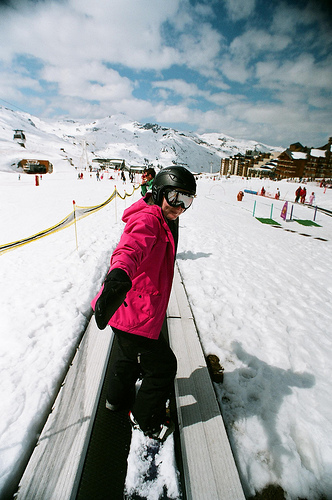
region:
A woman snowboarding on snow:
[96, 166, 197, 439]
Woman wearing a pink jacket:
[89, 167, 196, 340]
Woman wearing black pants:
[106, 328, 178, 443]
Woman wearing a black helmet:
[152, 164, 198, 207]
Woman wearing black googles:
[161, 187, 194, 210]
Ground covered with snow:
[0, 170, 331, 498]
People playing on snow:
[0, 168, 331, 210]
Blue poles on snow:
[251, 198, 275, 218]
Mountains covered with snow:
[0, 106, 275, 169]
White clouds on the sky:
[0, 0, 331, 133]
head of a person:
[141, 155, 212, 219]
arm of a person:
[107, 225, 146, 274]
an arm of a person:
[105, 227, 151, 281]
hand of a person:
[88, 270, 145, 320]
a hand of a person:
[80, 286, 134, 329]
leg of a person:
[114, 336, 192, 408]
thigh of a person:
[115, 325, 177, 369]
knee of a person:
[152, 351, 177, 369]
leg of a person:
[132, 368, 166, 417]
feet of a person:
[111, 401, 173, 430]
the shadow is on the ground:
[178, 345, 294, 428]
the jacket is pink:
[96, 201, 164, 334]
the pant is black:
[113, 330, 166, 428]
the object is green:
[257, 211, 276, 228]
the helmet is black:
[151, 170, 201, 201]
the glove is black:
[92, 270, 119, 327]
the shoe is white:
[106, 400, 126, 409]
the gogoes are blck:
[162, 191, 196, 209]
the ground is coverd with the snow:
[194, 234, 331, 479]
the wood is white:
[176, 321, 242, 499]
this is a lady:
[94, 160, 209, 423]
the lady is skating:
[83, 157, 205, 430]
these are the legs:
[99, 337, 177, 435]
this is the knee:
[143, 337, 178, 400]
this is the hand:
[87, 252, 140, 314]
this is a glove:
[82, 274, 129, 322]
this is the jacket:
[132, 229, 171, 293]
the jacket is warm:
[126, 231, 174, 286]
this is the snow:
[254, 293, 318, 374]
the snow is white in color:
[243, 269, 310, 331]